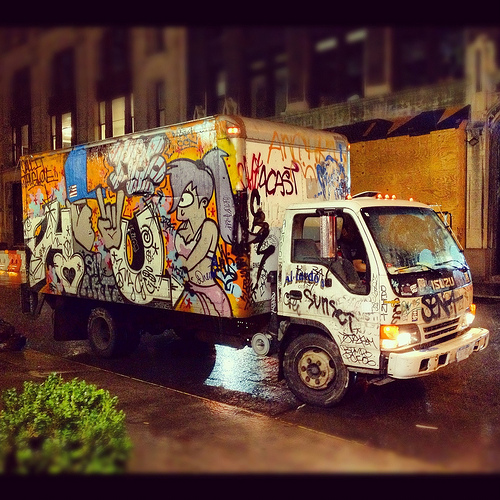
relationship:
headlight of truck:
[378, 324, 422, 357] [16, 109, 490, 411]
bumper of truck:
[379, 324, 492, 379] [16, 109, 490, 411]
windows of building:
[0, 75, 155, 175] [6, 31, 499, 231]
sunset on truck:
[302, 287, 356, 334] [16, 109, 490, 411]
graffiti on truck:
[171, 270, 233, 318] [16, 109, 490, 411]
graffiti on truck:
[284, 270, 320, 315] [33, 104, 465, 402]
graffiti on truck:
[341, 332, 371, 361] [16, 109, 490, 411]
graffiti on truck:
[21, 162, 236, 315] [16, 109, 490, 411]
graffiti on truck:
[23, 135, 474, 365] [16, 109, 490, 411]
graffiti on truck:
[29, 146, 220, 299] [16, 109, 490, 411]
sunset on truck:
[303, 287, 356, 329] [16, 109, 490, 411]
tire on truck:
[283, 335, 350, 408] [16, 109, 490, 411]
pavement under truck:
[0, 273, 499, 470] [9, 119, 487, 439]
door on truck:
[275, 208, 382, 370] [16, 109, 490, 411]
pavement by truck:
[0, 273, 499, 473] [16, 109, 490, 411]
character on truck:
[167, 145, 250, 317] [16, 109, 490, 411]